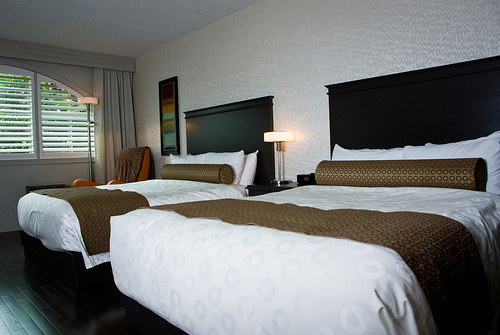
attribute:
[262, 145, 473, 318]
bed — made, brown, white, spread, fancy, neat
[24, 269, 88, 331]
floor — wood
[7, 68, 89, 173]
window — open, white, big, large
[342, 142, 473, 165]
pillow — brown, rolled, long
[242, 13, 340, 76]
weall — white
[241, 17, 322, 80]
wall — clean, white, spotless, close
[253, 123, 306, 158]
lamp — on, yellow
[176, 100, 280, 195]
headboard — black, wooden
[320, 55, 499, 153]
headboard — black, wooden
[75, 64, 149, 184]
curtain — white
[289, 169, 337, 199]
clock — alarm